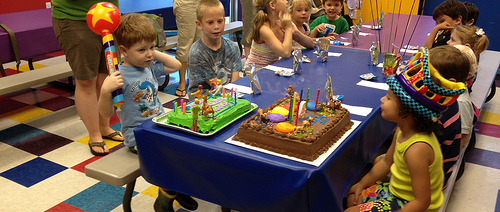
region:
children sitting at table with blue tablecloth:
[92, 0, 478, 197]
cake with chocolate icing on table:
[241, 90, 357, 158]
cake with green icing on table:
[160, 67, 246, 132]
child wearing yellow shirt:
[361, 47, 459, 207]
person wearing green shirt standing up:
[50, 5, 130, 146]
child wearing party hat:
[371, 55, 433, 201]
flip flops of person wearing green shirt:
[85, 130, 138, 155]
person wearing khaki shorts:
[172, 2, 224, 88]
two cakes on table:
[142, 50, 347, 162]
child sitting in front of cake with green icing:
[96, 13, 196, 149]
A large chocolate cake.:
[230, 92, 353, 162]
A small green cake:
[165, 92, 252, 132]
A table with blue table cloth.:
[130, 39, 423, 210]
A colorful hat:
[387, 45, 467, 125]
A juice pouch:
[291, 46, 302, 74]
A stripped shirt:
[431, 99, 460, 191]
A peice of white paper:
[355, 77, 389, 89]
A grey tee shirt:
[185, 37, 242, 89]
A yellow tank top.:
[389, 126, 445, 209]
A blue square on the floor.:
[0, 155, 68, 188]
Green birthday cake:
[167, 83, 240, 134]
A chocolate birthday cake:
[235, 81, 350, 162]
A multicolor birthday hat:
[388, 40, 465, 123]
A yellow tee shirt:
[388, 135, 448, 204]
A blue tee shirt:
[111, 60, 165, 142]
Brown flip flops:
[82, 125, 125, 163]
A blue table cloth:
[141, 130, 314, 205]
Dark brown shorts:
[55, 15, 100, 80]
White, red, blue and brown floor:
[17, 135, 84, 208]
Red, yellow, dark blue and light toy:
[78, 3, 133, 104]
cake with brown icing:
[227, 71, 362, 167]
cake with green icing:
[151, 81, 259, 138]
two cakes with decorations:
[150, 70, 362, 165]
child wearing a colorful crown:
[343, 45, 470, 209]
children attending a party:
[85, 1, 488, 210]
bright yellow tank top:
[387, 125, 445, 208]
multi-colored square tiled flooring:
[2, 94, 124, 209]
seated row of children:
[344, 0, 489, 210]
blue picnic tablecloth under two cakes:
[136, 40, 415, 210]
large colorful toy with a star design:
[85, 0, 125, 107]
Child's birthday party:
[81, 2, 494, 210]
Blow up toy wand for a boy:
[85, 0, 126, 121]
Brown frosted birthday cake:
[236, 86, 356, 165]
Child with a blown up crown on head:
[375, 45, 474, 142]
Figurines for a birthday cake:
[186, 90, 219, 139]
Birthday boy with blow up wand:
[87, 5, 172, 127]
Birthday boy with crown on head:
[373, 46, 468, 210]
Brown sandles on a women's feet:
[77, 128, 124, 156]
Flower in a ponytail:
[470, 25, 490, 46]